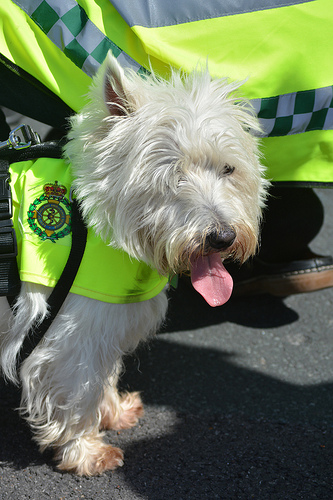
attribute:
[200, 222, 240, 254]
nose — black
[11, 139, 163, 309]
cloth — green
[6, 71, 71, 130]
fabric — black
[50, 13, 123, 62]
fabric — black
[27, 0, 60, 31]
fabric — black, square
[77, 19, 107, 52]
square — silver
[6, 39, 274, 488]
dog — hot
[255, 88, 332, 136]
cloth — grey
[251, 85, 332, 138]
cloth — grey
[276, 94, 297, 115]
cloth — grey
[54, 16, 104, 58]
cloth — grey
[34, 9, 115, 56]
cloth — grey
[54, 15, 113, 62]
cloth — grey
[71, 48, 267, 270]
face — shaggy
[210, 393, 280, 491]
concrete — standing on concrete